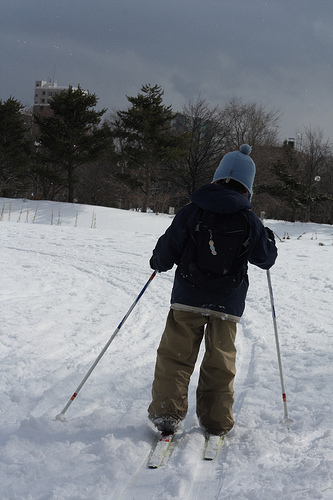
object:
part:
[276, 360, 284, 375]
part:
[158, 437, 170, 449]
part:
[211, 438, 223, 450]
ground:
[8, 245, 118, 500]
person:
[149, 141, 277, 439]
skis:
[147, 434, 178, 468]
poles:
[59, 255, 172, 417]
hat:
[211, 144, 257, 197]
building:
[30, 63, 225, 151]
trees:
[28, 77, 107, 207]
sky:
[43, 14, 237, 76]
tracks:
[54, 241, 137, 292]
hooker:
[207, 230, 217, 256]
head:
[211, 143, 256, 201]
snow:
[20, 423, 331, 487]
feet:
[146, 402, 180, 441]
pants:
[145, 302, 237, 435]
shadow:
[23, 399, 154, 451]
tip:
[239, 141, 251, 156]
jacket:
[149, 179, 276, 320]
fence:
[6, 199, 101, 228]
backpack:
[176, 191, 252, 293]